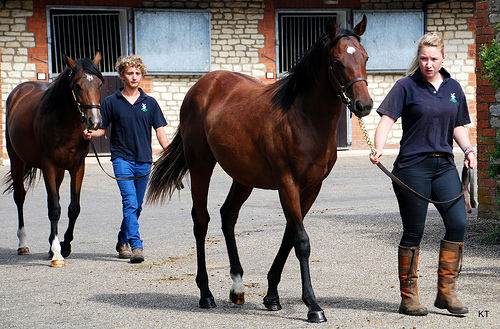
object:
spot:
[84, 73, 94, 82]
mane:
[286, 26, 359, 73]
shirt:
[375, 66, 472, 169]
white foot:
[228, 274, 246, 306]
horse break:
[339, 75, 375, 119]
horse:
[0, 51, 104, 268]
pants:
[389, 150, 468, 248]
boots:
[433, 236, 469, 314]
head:
[405, 34, 445, 77]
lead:
[357, 116, 480, 215]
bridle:
[324, 66, 368, 104]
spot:
[346, 46, 356, 55]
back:
[219, 74, 272, 124]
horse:
[141, 13, 374, 324]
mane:
[45, 59, 105, 80]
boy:
[82, 54, 171, 264]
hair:
[418, 31, 441, 43]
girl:
[368, 32, 479, 317]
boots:
[397, 242, 430, 315]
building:
[0, 6, 475, 167]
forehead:
[339, 33, 368, 69]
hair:
[116, 57, 146, 68]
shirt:
[97, 86, 169, 164]